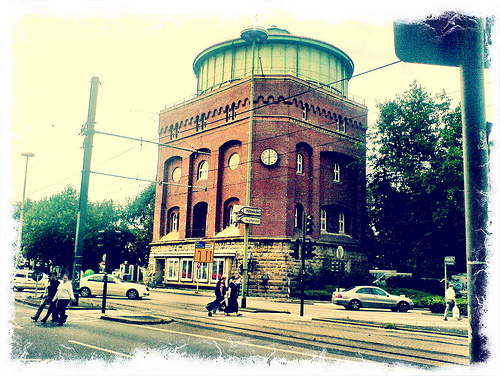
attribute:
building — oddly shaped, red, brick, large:
[143, 23, 367, 299]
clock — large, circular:
[262, 147, 279, 168]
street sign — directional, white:
[232, 205, 262, 227]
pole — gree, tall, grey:
[240, 223, 250, 308]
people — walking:
[32, 273, 75, 325]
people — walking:
[207, 275, 242, 316]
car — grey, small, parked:
[331, 283, 414, 311]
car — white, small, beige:
[79, 273, 151, 300]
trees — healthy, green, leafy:
[13, 79, 463, 288]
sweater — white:
[52, 279, 75, 302]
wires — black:
[13, 60, 493, 203]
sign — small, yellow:
[193, 241, 215, 265]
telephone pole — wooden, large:
[71, 77, 100, 304]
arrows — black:
[197, 250, 214, 260]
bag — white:
[451, 305, 460, 322]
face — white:
[263, 150, 276, 164]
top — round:
[191, 23, 354, 97]